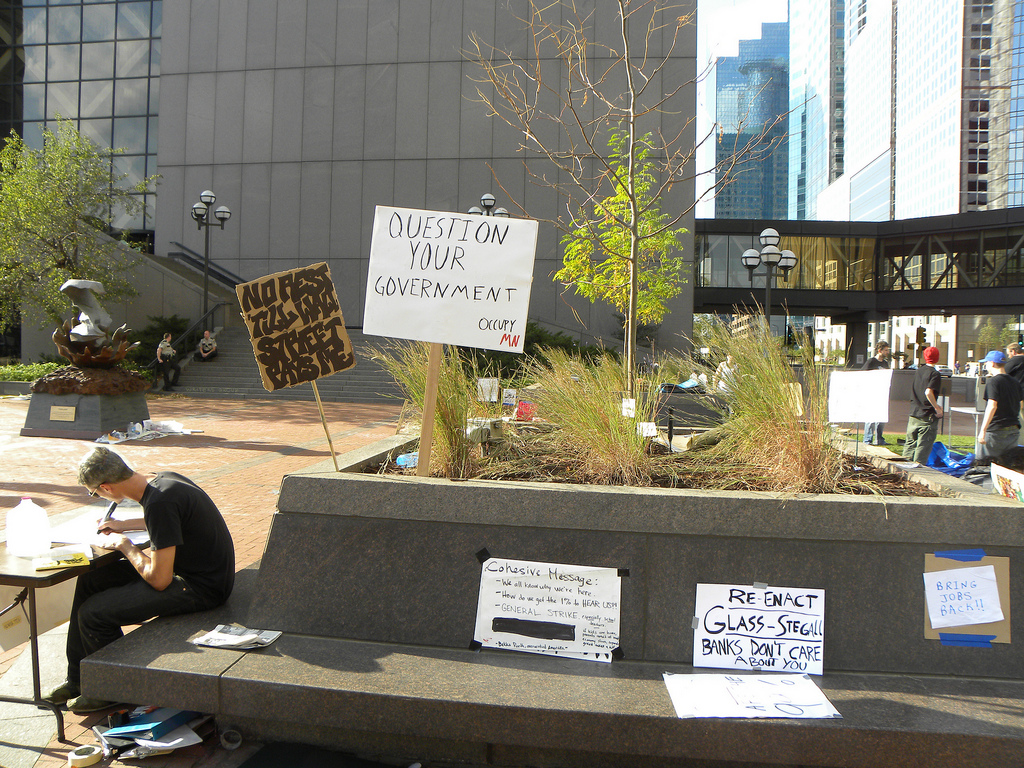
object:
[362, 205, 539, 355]
sign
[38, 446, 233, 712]
person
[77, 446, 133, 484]
gray hair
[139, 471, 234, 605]
black shirt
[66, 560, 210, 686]
pants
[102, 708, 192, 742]
blue notebook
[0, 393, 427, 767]
ground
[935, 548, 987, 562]
blue tape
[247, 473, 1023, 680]
wall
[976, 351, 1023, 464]
person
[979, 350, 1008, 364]
blue hat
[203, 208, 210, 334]
light pole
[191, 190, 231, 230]
three lights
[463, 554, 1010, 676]
three signs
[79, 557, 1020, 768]
bench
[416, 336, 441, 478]
stick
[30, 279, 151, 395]
statue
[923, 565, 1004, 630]
paper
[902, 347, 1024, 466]
two people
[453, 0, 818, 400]
tree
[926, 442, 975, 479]
chairs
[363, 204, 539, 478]
posterboard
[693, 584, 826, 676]
white sign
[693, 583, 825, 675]
black writing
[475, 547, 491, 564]
black tape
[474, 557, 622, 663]
white sign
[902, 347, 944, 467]
person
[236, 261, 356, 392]
black writing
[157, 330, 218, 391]
two police officers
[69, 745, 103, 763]
duct tape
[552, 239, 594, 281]
leaves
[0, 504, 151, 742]
table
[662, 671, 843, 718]
sign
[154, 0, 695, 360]
wall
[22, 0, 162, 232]
windows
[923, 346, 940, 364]
head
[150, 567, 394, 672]
shadow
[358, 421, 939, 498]
dirt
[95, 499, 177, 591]
left arm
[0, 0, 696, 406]
building